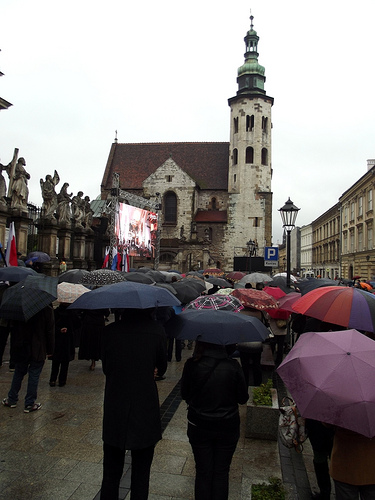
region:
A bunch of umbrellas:
[7, 226, 369, 389]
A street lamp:
[263, 189, 321, 273]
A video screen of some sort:
[101, 181, 169, 256]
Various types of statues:
[2, 167, 100, 239]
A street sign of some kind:
[247, 240, 284, 267]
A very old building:
[138, 170, 265, 233]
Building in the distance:
[303, 203, 370, 258]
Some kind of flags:
[97, 233, 124, 267]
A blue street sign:
[249, 233, 282, 272]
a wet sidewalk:
[15, 420, 63, 478]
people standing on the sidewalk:
[2, 239, 371, 499]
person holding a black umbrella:
[175, 303, 259, 499]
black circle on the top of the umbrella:
[344, 346, 354, 358]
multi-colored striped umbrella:
[284, 286, 374, 331]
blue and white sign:
[262, 244, 280, 265]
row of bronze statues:
[1, 154, 102, 226]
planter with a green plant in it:
[244, 379, 282, 437]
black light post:
[277, 194, 303, 288]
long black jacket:
[86, 317, 167, 456]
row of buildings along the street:
[286, 156, 373, 286]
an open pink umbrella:
[269, 331, 372, 445]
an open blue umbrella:
[169, 306, 257, 363]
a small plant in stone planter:
[232, 379, 280, 452]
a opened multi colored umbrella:
[278, 281, 372, 337]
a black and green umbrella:
[12, 275, 60, 331]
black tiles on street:
[152, 371, 182, 463]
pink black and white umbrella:
[171, 286, 242, 317]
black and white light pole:
[258, 191, 303, 279]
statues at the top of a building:
[12, 155, 83, 223]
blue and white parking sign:
[246, 241, 282, 277]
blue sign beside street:
[261, 245, 280, 260]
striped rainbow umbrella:
[298, 278, 373, 324]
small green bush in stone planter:
[253, 378, 274, 404]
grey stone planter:
[248, 382, 281, 438]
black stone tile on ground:
[161, 392, 178, 412]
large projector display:
[114, 202, 158, 255]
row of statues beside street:
[6, 158, 97, 236]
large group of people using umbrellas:
[8, 235, 373, 433]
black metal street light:
[278, 196, 298, 235]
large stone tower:
[225, 5, 282, 185]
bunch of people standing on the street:
[2, 247, 374, 498]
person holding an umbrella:
[175, 299, 259, 498]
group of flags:
[98, 241, 131, 274]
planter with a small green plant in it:
[242, 379, 281, 440]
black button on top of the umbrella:
[344, 349, 353, 358]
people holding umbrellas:
[4, 248, 374, 498]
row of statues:
[6, 149, 102, 232]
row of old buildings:
[272, 161, 372, 285]